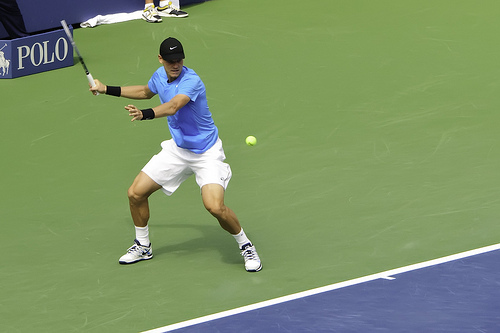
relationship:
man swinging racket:
[88, 36, 263, 273] [62, 19, 100, 95]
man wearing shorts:
[88, 36, 263, 273] [141, 133, 232, 195]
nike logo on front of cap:
[168, 44, 179, 51] [159, 36, 185, 63]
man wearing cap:
[88, 36, 263, 273] [159, 36, 185, 63]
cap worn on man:
[159, 36, 185, 63] [88, 36, 263, 273]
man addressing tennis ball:
[88, 36, 263, 273] [244, 134, 258, 147]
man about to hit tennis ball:
[88, 36, 263, 273] [244, 134, 258, 147]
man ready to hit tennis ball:
[88, 36, 263, 273] [244, 134, 258, 147]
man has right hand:
[88, 36, 263, 273] [86, 78, 107, 97]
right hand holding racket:
[86, 78, 107, 97] [62, 19, 100, 95]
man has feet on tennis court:
[88, 36, 263, 273] [1, 0, 499, 333]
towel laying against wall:
[79, 7, 145, 28] [1, 1, 204, 39]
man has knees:
[88, 36, 263, 273] [126, 186, 225, 216]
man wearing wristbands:
[88, 36, 263, 273] [105, 84, 155, 120]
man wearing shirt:
[88, 36, 263, 273] [146, 65, 218, 156]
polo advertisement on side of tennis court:
[16, 37, 69, 74] [1, 0, 499, 333]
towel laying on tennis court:
[79, 7, 145, 28] [1, 0, 499, 333]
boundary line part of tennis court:
[132, 240, 499, 332] [1, 0, 499, 333]